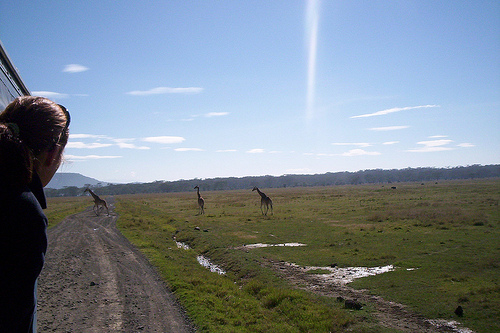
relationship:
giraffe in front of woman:
[84, 186, 110, 217] [0, 96, 71, 333]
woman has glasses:
[0, 96, 71, 333] [55, 103, 72, 144]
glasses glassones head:
[55, 103, 72, 144] [1, 95, 70, 187]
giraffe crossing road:
[83, 184, 113, 216] [31, 200, 190, 332]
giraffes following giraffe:
[192, 185, 274, 218] [83, 184, 113, 216]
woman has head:
[0, 96, 71, 333] [1, 95, 70, 187]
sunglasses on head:
[55, 103, 72, 144] [1, 95, 70, 187]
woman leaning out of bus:
[0, 96, 71, 333] [0, 42, 30, 126]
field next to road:
[108, 178, 499, 332] [31, 200, 190, 332]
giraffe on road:
[83, 184, 113, 216] [31, 200, 190, 332]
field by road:
[108, 178, 499, 332] [31, 200, 190, 332]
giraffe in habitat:
[83, 184, 113, 216] [32, 161, 500, 332]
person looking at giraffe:
[0, 96, 71, 333] [84, 186, 110, 217]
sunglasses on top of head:
[55, 103, 72, 144] [1, 95, 70, 187]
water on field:
[171, 236, 417, 294] [108, 178, 499, 332]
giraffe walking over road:
[83, 184, 113, 216] [31, 200, 190, 332]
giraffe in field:
[249, 184, 277, 216] [108, 178, 499, 332]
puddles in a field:
[237, 241, 420, 290] [108, 178, 499, 332]